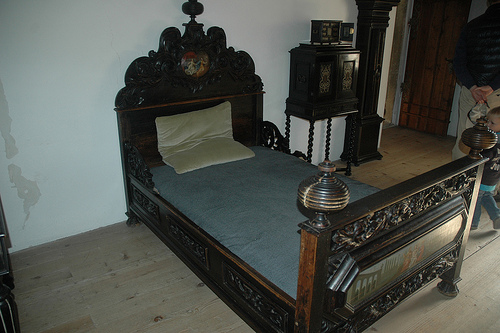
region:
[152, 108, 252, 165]
pillow on the bed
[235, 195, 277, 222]
sheet on the bed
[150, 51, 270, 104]
headboard of the bed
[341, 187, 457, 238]
tailboard of the bed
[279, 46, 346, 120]
stand next to bed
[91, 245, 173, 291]
the floor is wood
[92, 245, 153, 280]
the floor is tan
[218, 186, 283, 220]
the sheets are blue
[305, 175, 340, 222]
pole of the bed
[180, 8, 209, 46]
pole of the bed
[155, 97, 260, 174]
a pillow on bed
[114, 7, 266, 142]
the headboard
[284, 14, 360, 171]
the chest beside the bed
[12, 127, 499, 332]
the oak floors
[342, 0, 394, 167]
the grandfather clock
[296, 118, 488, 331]
the small footboard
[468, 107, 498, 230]
a child walking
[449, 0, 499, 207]
the man on the right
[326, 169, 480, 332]
a design on the footboard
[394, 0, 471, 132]
a wooden door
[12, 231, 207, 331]
the floor is wooden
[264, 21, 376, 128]
the cabinet beside the bed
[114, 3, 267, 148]
the headboard is wooden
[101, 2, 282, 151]
the headboard is carved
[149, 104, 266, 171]
the pillow on the bed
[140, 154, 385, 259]
the bed is made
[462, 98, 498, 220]
child beside the bed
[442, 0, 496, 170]
the person beside the child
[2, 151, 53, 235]
the spot on the wall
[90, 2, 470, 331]
detailed carvings in the dark wood bed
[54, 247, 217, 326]
dark wood stained bed on light stained wood floor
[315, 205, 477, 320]
framed mural on the foot board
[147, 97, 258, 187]
thin folded white velvet pillow on bed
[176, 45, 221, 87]
framed portrait on the head board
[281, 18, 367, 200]
dark stained wood jewelry chest on floor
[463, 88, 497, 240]
small male child wearing jeans and shirt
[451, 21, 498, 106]
man wearing puffy black fabric coat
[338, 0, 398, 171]
bottom half of a grandfather clock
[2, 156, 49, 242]
paint peeling off of the white wall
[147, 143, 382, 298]
the mattress on the bed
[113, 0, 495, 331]
the frame of the bed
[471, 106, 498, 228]
the child near the bed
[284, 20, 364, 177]
the furniture next to the bed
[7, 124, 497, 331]
the wood on the floor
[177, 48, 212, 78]
the picture on the head board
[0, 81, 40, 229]
the paint peeling off the wall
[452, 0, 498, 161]
the adult standing next to the child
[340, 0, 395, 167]
the grandfather clock against the wall